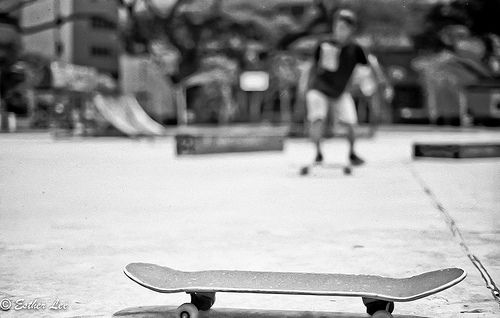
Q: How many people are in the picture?
A: One.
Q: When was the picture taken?
A: Daytime.